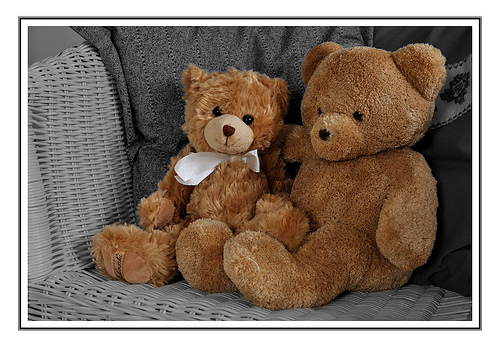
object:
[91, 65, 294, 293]
teddy bear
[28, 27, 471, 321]
chair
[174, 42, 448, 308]
teddy bear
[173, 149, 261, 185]
bow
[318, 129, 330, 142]
nose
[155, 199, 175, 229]
front paw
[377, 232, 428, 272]
front paw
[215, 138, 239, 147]
mouth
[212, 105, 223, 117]
eye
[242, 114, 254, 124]
eye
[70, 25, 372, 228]
blanket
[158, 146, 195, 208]
arm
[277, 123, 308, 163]
arm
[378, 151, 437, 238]
arm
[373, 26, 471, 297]
blanket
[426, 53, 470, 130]
trim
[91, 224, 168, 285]
paw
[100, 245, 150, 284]
pad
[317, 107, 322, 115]
eye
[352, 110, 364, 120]
eye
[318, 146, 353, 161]
mouth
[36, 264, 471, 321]
seat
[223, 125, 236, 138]
nose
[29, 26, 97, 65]
wall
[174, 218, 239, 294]
leg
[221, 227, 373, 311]
leg